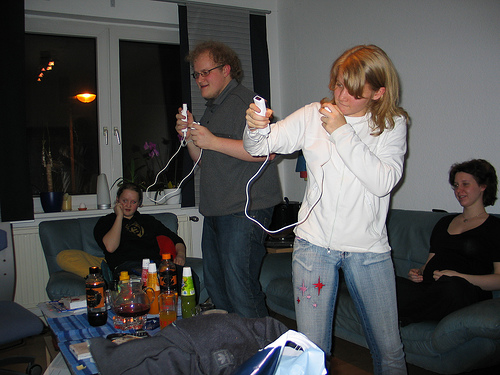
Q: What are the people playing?
A: Games.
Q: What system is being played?
A: Wii.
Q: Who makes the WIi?
A: Nintendo.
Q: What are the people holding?
A: Controllers.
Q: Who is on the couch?
A: A woman.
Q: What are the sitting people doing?
A: Watching.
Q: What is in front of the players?
A: Drinks.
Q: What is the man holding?
A: A game controller.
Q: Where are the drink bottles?
A: On the table.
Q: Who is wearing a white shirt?
A: A woman.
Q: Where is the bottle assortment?
A: On table.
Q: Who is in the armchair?
A: A woman.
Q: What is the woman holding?
A: A gaming controller.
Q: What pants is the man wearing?
A: Blue jeans.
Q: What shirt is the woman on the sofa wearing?
A: Black.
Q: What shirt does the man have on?
A: Grey.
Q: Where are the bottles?
A: On the table.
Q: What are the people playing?
A: A wii game.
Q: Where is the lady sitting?
A: On the sofa.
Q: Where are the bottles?
A: On the table.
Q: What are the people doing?
A: Playing video games.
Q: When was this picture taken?
A: At night.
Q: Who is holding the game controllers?
A: The man and the woman in the center.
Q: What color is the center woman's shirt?
A: White.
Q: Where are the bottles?
A: On the table.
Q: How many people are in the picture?
A: Four.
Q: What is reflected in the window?
A: Lights.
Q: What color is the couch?
A: Blue.